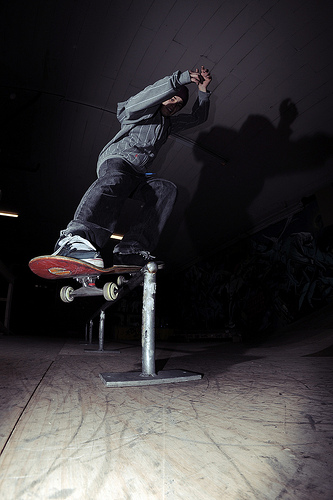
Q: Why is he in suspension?
A: Trying a trick.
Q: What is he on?
A: Skateboard.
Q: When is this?
A: Night.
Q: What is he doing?
A: Skating.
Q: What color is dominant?
A: Black.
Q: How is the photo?
A: Clear.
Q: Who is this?
A: Person.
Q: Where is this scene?
A: Skate park.